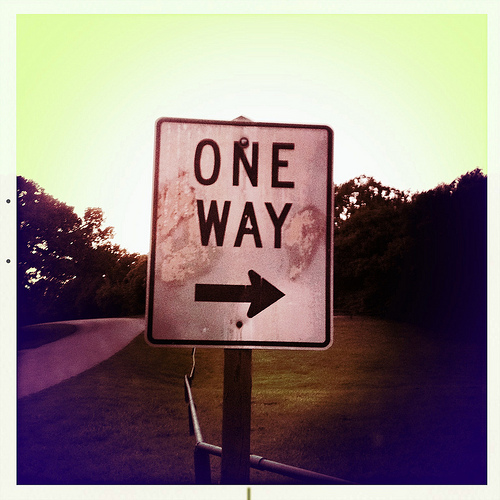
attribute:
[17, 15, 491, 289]
sky — clear, bright, yellow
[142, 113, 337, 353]
sign — white, one way, dirty, rectangular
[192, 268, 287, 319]
arrow — black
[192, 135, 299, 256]
lettering — black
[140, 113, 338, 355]
edging — black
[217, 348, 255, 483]
pole — wooden, dark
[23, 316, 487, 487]
grass — green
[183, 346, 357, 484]
fence — metal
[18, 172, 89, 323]
tree — leafy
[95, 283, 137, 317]
tree — leafy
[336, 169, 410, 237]
tree — leafy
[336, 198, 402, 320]
tree — leafy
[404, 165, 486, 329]
tree — leafy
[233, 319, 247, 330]
bolt — metal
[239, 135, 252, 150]
bolt — metal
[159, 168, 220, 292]
mark — black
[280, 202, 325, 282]
mark — black